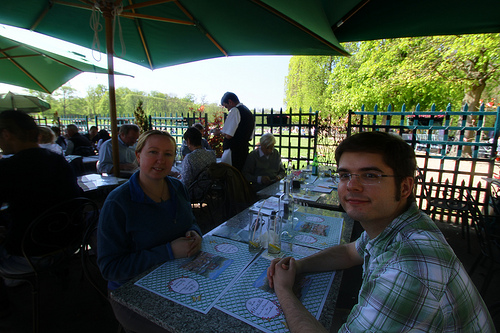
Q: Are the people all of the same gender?
A: No, they are both male and female.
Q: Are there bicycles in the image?
A: No, there are no bicycles.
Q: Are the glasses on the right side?
A: Yes, the glasses are on the right of the image.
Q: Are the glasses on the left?
A: No, the glasses are on the right of the image.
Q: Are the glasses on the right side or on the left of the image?
A: The glasses are on the right of the image.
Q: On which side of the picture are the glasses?
A: The glasses are on the right of the image.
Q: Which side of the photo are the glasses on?
A: The glasses are on the right of the image.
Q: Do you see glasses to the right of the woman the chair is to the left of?
A: Yes, there are glasses to the right of the woman.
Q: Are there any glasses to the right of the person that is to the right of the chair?
A: Yes, there are glasses to the right of the woman.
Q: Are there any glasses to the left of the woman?
A: No, the glasses are to the right of the woman.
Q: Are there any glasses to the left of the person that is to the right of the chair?
A: No, the glasses are to the right of the woman.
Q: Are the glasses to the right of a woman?
A: Yes, the glasses are to the right of a woman.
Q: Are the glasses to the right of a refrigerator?
A: No, the glasses are to the right of a woman.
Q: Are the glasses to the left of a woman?
A: No, the glasses are to the right of a woman.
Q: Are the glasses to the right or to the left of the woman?
A: The glasses are to the right of the woman.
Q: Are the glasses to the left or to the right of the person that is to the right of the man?
A: The glasses are to the right of the woman.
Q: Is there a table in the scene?
A: Yes, there is a table.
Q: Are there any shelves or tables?
A: Yes, there is a table.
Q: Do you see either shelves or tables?
A: Yes, there is a table.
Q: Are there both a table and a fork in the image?
A: No, there is a table but no forks.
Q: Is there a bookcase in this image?
A: No, there are no bookcases.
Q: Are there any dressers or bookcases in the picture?
A: No, there are no bookcases or dressers.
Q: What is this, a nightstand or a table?
A: This is a table.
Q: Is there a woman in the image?
A: Yes, there is a woman.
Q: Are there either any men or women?
A: Yes, there is a woman.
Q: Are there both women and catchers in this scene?
A: No, there is a woman but no catchers.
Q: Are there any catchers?
A: No, there are no catchers.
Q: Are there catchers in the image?
A: No, there are no catchers.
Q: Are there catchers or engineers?
A: No, there are no catchers or engineers.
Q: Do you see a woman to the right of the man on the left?
A: Yes, there is a woman to the right of the man.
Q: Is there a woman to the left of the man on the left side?
A: No, the woman is to the right of the man.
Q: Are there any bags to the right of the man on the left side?
A: No, there is a woman to the right of the man.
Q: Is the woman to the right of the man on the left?
A: Yes, the woman is to the right of the man.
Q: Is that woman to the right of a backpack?
A: No, the woman is to the right of the man.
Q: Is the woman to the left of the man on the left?
A: No, the woman is to the right of the man.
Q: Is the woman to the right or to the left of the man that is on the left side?
A: The woman is to the right of the man.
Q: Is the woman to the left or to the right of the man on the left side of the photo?
A: The woman is to the right of the man.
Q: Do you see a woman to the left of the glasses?
A: Yes, there is a woman to the left of the glasses.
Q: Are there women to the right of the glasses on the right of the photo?
A: No, the woman is to the left of the glasses.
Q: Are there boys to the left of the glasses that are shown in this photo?
A: No, there is a woman to the left of the glasses.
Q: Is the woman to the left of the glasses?
A: Yes, the woman is to the left of the glasses.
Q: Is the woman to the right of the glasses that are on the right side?
A: No, the woman is to the left of the glasses.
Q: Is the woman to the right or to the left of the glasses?
A: The woman is to the left of the glasses.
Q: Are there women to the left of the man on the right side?
A: Yes, there is a woman to the left of the man.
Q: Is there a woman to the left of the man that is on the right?
A: Yes, there is a woman to the left of the man.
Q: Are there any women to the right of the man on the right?
A: No, the woman is to the left of the man.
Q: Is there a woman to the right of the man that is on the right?
A: No, the woman is to the left of the man.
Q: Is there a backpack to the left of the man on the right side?
A: No, there is a woman to the left of the man.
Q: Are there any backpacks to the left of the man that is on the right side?
A: No, there is a woman to the left of the man.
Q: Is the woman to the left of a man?
A: Yes, the woman is to the left of a man.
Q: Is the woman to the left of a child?
A: No, the woman is to the left of a man.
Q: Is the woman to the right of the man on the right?
A: No, the woman is to the left of the man.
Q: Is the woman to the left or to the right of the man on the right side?
A: The woman is to the left of the man.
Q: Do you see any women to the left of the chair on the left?
A: No, the woman is to the right of the chair.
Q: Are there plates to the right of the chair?
A: No, there is a woman to the right of the chair.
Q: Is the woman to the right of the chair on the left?
A: Yes, the woman is to the right of the chair.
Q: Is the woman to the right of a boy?
A: No, the woman is to the right of the chair.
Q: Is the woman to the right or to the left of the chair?
A: The woman is to the right of the chair.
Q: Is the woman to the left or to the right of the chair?
A: The woman is to the right of the chair.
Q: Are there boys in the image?
A: No, there are no boys.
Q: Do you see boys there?
A: No, there are no boys.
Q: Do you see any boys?
A: No, there are no boys.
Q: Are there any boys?
A: No, there are no boys.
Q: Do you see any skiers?
A: No, there are no skiers.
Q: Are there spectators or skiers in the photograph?
A: No, there are no skiers or spectators.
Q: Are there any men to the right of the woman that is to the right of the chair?
A: Yes, there is a man to the right of the woman.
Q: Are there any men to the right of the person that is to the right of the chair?
A: Yes, there is a man to the right of the woman.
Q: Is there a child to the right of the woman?
A: No, there is a man to the right of the woman.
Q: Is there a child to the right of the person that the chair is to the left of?
A: No, there is a man to the right of the woman.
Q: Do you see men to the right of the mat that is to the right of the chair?
A: Yes, there is a man to the right of the mat.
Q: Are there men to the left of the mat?
A: No, the man is to the right of the mat.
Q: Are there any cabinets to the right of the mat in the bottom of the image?
A: No, there is a man to the right of the mat.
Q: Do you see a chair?
A: Yes, there is a chair.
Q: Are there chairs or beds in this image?
A: Yes, there is a chair.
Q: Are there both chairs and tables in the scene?
A: Yes, there are both a chair and a table.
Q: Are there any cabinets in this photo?
A: No, there are no cabinets.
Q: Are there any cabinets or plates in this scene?
A: No, there are no cabinets or plates.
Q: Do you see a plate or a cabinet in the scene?
A: No, there are no cabinets or plates.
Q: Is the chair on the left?
A: Yes, the chair is on the left of the image.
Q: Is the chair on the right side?
A: No, the chair is on the left of the image.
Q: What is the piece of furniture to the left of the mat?
A: The piece of furniture is a chair.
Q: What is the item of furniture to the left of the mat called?
A: The piece of furniture is a chair.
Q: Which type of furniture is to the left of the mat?
A: The piece of furniture is a chair.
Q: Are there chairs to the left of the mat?
A: Yes, there is a chair to the left of the mat.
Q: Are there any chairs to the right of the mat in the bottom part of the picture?
A: No, the chair is to the left of the mat.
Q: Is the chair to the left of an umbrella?
A: No, the chair is to the left of a mat.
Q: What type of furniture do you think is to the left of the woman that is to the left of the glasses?
A: The piece of furniture is a chair.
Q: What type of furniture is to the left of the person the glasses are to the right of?
A: The piece of furniture is a chair.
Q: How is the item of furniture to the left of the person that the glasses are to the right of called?
A: The piece of furniture is a chair.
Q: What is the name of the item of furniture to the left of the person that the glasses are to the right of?
A: The piece of furniture is a chair.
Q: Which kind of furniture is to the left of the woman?
A: The piece of furniture is a chair.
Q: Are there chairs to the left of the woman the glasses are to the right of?
A: Yes, there is a chair to the left of the woman.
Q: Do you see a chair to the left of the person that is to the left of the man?
A: Yes, there is a chair to the left of the woman.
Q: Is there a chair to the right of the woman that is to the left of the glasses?
A: No, the chair is to the left of the woman.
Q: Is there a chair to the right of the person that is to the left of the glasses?
A: No, the chair is to the left of the woman.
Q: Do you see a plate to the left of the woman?
A: No, there is a chair to the left of the woman.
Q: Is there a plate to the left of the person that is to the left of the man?
A: No, there is a chair to the left of the woman.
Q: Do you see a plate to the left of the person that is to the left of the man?
A: No, there is a chair to the left of the woman.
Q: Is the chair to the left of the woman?
A: Yes, the chair is to the left of the woman.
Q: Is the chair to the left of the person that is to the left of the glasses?
A: Yes, the chair is to the left of the woman.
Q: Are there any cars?
A: No, there are no cars.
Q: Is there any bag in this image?
A: No, there are no bags.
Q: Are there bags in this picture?
A: No, there are no bags.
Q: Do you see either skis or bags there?
A: No, there are no bags or skis.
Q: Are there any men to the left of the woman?
A: Yes, there is a man to the left of the woman.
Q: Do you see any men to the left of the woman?
A: Yes, there is a man to the left of the woman.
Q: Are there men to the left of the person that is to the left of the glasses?
A: Yes, there is a man to the left of the woman.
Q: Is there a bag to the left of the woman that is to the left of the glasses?
A: No, there is a man to the left of the woman.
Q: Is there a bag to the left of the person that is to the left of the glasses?
A: No, there is a man to the left of the woman.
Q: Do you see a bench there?
A: No, there are no benches.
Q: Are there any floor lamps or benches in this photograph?
A: No, there are no benches or floor lamps.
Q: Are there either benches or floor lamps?
A: No, there are no benches or floor lamps.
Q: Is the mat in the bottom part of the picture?
A: Yes, the mat is in the bottom of the image.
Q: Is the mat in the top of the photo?
A: No, the mat is in the bottom of the image.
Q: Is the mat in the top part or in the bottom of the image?
A: The mat is in the bottom of the image.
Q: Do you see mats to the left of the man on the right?
A: Yes, there is a mat to the left of the man.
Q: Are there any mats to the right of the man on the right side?
A: No, the mat is to the left of the man.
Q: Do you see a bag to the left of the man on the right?
A: No, there is a mat to the left of the man.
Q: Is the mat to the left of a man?
A: Yes, the mat is to the left of a man.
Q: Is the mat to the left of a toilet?
A: No, the mat is to the left of a man.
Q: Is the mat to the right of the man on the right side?
A: No, the mat is to the left of the man.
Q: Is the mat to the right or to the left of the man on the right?
A: The mat is to the left of the man.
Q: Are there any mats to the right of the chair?
A: Yes, there is a mat to the right of the chair.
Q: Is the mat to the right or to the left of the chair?
A: The mat is to the right of the chair.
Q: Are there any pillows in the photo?
A: No, there are no pillows.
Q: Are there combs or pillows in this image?
A: No, there are no pillows or combs.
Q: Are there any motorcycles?
A: No, there are no motorcycles.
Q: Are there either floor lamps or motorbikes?
A: No, there are no motorbikes or floor lamps.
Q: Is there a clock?
A: No, there are no clocks.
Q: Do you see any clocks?
A: No, there are no clocks.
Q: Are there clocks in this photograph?
A: No, there are no clocks.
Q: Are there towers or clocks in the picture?
A: No, there are no clocks or towers.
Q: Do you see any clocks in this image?
A: No, there are no clocks.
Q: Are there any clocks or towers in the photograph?
A: No, there are no clocks or towers.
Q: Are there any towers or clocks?
A: No, there are no clocks or towers.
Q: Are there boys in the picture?
A: No, there are no boys.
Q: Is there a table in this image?
A: Yes, there is a table.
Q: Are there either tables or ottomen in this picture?
A: Yes, there is a table.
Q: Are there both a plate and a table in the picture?
A: No, there is a table but no plates.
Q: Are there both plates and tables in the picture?
A: No, there is a table but no plates.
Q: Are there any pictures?
A: No, there are no pictures.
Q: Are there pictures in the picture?
A: No, there are no pictures.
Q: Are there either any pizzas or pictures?
A: No, there are no pictures or pizzas.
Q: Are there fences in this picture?
A: Yes, there is a fence.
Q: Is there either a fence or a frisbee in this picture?
A: Yes, there is a fence.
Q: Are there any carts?
A: No, there are no carts.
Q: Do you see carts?
A: No, there are no carts.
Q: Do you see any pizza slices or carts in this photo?
A: No, there are no carts or pizza slices.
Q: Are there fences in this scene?
A: Yes, there is a fence.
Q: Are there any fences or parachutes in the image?
A: Yes, there is a fence.